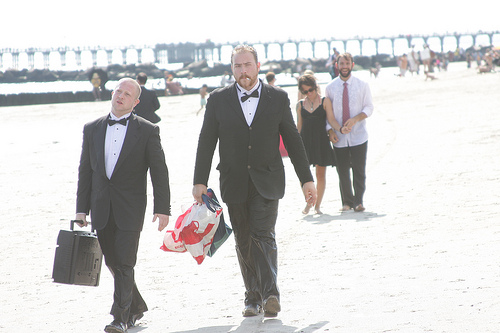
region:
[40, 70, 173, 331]
person walking on a beach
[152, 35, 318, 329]
person walking on a beach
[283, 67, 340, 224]
person walking on a beach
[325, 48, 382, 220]
person walking on a beach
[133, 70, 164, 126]
person walking on a beach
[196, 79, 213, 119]
person walking on a beach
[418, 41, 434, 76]
person walking on a beach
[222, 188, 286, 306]
pair of black pants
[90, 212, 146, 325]
pair of black pants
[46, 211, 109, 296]
large black plastic radio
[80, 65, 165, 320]
man wearing a tie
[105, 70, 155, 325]
man wearing black coat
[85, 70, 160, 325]
man wearing black pants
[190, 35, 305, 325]
man wearing black coat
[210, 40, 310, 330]
man wearing black pants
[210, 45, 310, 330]
man wearing black tie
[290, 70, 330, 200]
woman wearing black dress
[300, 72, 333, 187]
woman wearing sun shades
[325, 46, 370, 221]
man wearing white shirt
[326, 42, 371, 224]
man wearing a tie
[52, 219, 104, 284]
A stereo being carried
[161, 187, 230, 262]
A few bags being carried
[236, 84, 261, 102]
A bow tie on a neck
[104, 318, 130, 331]
Dress shoe on a foot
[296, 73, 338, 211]
Lady wearing a dress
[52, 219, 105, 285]
A black stereo in hand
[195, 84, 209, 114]
Man having fun on a beach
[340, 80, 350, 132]
A red tie being worn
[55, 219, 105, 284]
A boombox in someone's hand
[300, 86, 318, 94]
Sunglasses being worn by a girl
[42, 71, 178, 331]
Man in suit casing a black case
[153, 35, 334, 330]
man in suit carrying a bunch of plastic bags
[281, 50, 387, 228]
couple walking behind man with bags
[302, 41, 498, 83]
Crowd of people in the background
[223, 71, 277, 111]
man has a crooked bow tie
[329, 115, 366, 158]
man and woman holding hands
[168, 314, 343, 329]
man's shadow in the sand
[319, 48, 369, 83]
man with a very large smile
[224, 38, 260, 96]
man is smoking a cigarette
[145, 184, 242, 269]
red white and blue bags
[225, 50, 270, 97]
the head of a man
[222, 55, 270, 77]
the eyes of a man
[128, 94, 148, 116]
the ear of a man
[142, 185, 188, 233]
the hand of a man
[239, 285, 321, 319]
the feet of a man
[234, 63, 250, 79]
the nose of a man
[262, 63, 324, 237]
the arm of a man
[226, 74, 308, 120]
a man wearing a bow tie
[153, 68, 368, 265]
a man wearing a suit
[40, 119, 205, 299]
a man carrying a brief case